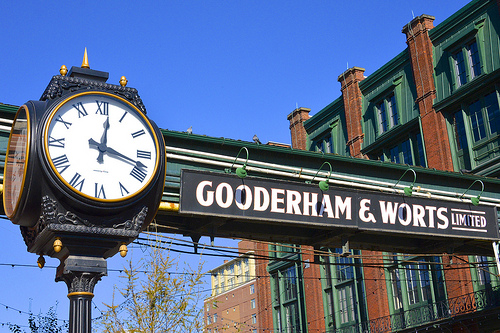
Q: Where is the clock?
A: On The pedestal.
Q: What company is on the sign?
A: Gooderham & worts limited.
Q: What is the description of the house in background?
A: Brown and green wall.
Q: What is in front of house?
A: A large clock.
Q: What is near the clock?
A: A company's name.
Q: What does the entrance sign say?
A: Gooderham & worts limited.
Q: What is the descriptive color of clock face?
A: White.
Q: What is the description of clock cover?
A: Black.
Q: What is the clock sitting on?
A: A black pole.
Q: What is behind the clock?
A: A tree.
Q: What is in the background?
A: Cables.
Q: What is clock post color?
A: Gray.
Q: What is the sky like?
A: Clear.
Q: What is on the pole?
A: Clock.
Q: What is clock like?
A: Art deco.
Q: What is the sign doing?
A: Hanging.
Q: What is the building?
A: Brick.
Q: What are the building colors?
A: Brown and green.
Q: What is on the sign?
A: Advertisement.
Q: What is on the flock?
A: Faces.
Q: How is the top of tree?
A: Yellow.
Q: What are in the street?
A: Buildings.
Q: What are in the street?
A: Clock.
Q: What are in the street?
A: Sky.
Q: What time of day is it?
A: Afternoon.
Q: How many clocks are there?
A: One.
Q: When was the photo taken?
A: Day time.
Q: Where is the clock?
A: A pole.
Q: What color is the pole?
A: Black.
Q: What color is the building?
A: Green.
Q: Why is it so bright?
A: Sunny.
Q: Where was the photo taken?
A: Outside of Gooderham & Worts Limited shop.